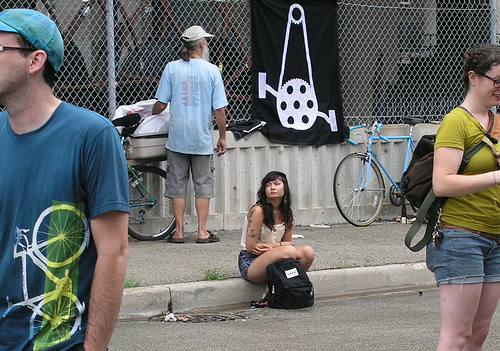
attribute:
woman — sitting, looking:
[235, 169, 316, 309]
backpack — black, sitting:
[262, 256, 316, 313]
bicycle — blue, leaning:
[330, 113, 437, 228]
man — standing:
[2, 3, 133, 350]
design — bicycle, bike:
[2, 199, 92, 349]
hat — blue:
[0, 6, 67, 77]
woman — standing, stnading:
[422, 44, 499, 349]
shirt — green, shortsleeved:
[432, 106, 500, 240]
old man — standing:
[149, 23, 227, 245]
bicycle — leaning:
[110, 110, 178, 242]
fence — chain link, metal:
[1, 2, 500, 138]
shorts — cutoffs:
[425, 225, 499, 289]